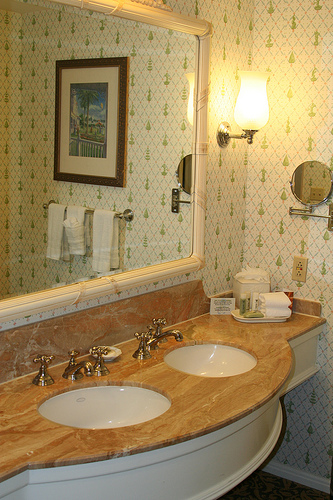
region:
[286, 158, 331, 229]
small circular mirror hanging on the wall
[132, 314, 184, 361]
silver faucet on the bathroom vanity counter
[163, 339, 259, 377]
white sink in the vanity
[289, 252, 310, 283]
tan outlet in the wall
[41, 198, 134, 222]
silver towel bar on the wall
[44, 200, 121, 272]
white towels on the towel bar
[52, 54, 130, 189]
picture with brown frame hanging on the wall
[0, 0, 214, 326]
rectangular mirror on the wall above the bathroom vanity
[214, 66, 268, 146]
white and silver light on the wall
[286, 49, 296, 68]
green tree on the wallpaper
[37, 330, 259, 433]
the sinks are white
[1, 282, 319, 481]
the counter top is brown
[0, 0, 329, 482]
the wall has wall paper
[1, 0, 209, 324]
the mirror is framed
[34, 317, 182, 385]
the fixtures are silver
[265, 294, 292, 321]
towels on a tray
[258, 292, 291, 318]
towels are white and folded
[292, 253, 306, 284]
the outlet is beige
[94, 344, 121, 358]
a soap dish on counter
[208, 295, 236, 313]
a sign on counter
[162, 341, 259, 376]
white ceramic bathroom sink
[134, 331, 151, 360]
silver metal sink handle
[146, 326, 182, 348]
silver metal sink faucet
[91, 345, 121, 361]
white soap dish on counter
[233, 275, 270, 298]
white plastic tissue holder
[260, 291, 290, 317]
white towels on tray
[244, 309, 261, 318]
green soap on tray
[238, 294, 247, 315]
plastic bottle on tray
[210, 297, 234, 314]
white card on counter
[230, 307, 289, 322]
white tray on counter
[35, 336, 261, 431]
two round white sinks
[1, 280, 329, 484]
a marble countertop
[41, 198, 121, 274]
white towels on a rack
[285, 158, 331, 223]
a round vanity mirror on a hinge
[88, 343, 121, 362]
small round soap dish on the counter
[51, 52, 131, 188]
painting on the wall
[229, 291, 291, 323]
tray with single serving toiletries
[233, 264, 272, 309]
a box of tissues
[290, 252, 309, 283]
an electrical outlet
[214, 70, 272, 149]
a lamp on the wall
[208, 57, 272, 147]
lamp mounted on the walls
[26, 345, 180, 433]
a bathroom sink with facuet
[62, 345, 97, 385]
the faucet head of a sink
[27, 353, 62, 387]
handles for a sink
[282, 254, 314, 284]
a power wall outlet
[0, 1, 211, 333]
mirror reflections on the mirror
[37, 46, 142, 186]
a painting reflected from the mirror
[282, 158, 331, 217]
a glass mounted on the walls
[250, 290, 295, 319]
stack of hand towels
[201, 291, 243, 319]
a card mounted on the counter top